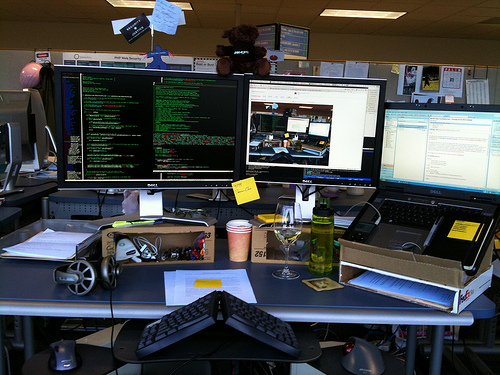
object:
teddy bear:
[215, 24, 271, 78]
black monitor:
[236, 72, 388, 182]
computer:
[240, 71, 387, 229]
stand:
[102, 219, 216, 266]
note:
[231, 177, 262, 206]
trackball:
[340, 338, 383, 374]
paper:
[0, 228, 90, 261]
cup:
[225, 219, 251, 263]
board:
[396, 62, 500, 104]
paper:
[439, 66, 464, 98]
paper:
[466, 78, 493, 105]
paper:
[396, 65, 423, 95]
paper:
[343, 62, 368, 80]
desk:
[0, 197, 497, 375]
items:
[0, 197, 470, 298]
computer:
[53, 62, 243, 231]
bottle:
[307, 197, 335, 275]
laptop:
[340, 103, 500, 276]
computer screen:
[50, 62, 245, 191]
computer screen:
[238, 72, 387, 189]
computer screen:
[378, 98, 500, 208]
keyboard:
[135, 290, 302, 360]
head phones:
[53, 254, 124, 296]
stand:
[249, 217, 344, 267]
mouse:
[49, 336, 83, 374]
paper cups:
[225, 219, 251, 263]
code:
[60, 73, 234, 180]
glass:
[272, 202, 303, 280]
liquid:
[274, 228, 302, 247]